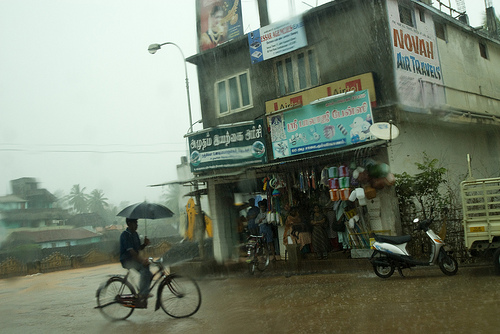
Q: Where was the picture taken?
A: In a city.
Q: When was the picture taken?
A: Daytime.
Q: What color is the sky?
A: Gray.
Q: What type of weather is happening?
A: Rain.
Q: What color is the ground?
A: Brown.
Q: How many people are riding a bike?
A: One.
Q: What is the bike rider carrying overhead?
A: An umbrella.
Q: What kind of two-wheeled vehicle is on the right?
A: A scooter.